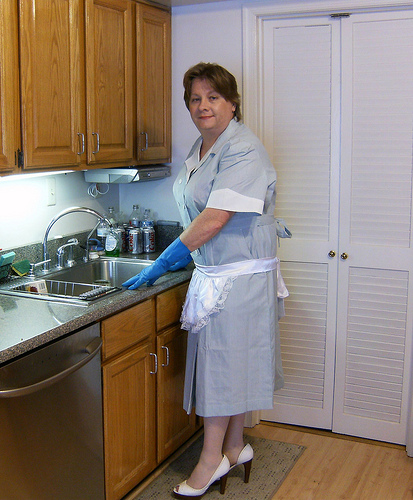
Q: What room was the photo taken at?
A: It was taken at the kitchen.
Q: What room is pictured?
A: It is a kitchen.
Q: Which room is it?
A: It is a kitchen.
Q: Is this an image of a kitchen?
A: Yes, it is showing a kitchen.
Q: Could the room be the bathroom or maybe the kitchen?
A: It is the kitchen.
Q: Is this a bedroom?
A: No, it is a kitchen.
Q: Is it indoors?
A: Yes, it is indoors.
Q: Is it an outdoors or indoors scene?
A: It is indoors.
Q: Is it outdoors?
A: No, it is indoors.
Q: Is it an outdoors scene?
A: No, it is indoors.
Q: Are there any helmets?
A: No, there are no helmets.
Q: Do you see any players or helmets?
A: No, there are no helmets or players.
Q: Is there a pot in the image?
A: No, there are no pots.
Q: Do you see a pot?
A: No, there are no pots.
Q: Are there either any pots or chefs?
A: No, there are no pots or chefs.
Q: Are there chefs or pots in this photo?
A: No, there are no pots or chefs.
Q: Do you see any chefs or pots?
A: No, there are no pots or chefs.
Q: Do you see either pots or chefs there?
A: No, there are no pots or chefs.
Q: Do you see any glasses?
A: No, there are no glasses.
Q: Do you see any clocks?
A: No, there are no clocks.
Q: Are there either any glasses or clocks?
A: No, there are no clocks or glasses.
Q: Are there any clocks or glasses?
A: No, there are no clocks or glasses.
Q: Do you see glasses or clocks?
A: No, there are no clocks or glasses.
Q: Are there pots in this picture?
A: No, there are no pots.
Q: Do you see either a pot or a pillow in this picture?
A: No, there are no pots or pillows.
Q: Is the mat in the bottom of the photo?
A: Yes, the mat is in the bottom of the image.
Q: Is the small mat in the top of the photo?
A: No, the mat is in the bottom of the image.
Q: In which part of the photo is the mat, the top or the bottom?
A: The mat is in the bottom of the image.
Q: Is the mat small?
A: Yes, the mat is small.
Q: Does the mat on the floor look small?
A: Yes, the mat is small.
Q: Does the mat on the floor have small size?
A: Yes, the mat is small.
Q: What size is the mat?
A: The mat is small.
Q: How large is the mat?
A: The mat is small.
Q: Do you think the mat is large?
A: No, the mat is small.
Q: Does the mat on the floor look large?
A: No, the mat is small.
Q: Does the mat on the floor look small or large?
A: The mat is small.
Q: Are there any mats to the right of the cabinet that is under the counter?
A: Yes, there is a mat to the right of the cabinet.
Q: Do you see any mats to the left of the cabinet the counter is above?
A: No, the mat is to the right of the cabinet.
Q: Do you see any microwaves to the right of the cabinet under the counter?
A: No, there is a mat to the right of the cabinet.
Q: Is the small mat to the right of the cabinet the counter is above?
A: Yes, the mat is to the right of the cabinet.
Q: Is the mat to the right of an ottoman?
A: No, the mat is to the right of the cabinet.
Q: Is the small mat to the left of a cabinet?
A: No, the mat is to the right of a cabinet.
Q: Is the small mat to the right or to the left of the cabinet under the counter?
A: The mat is to the right of the cabinet.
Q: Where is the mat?
A: The mat is on the floor.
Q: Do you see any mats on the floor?
A: Yes, there is a mat on the floor.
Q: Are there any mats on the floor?
A: Yes, there is a mat on the floor.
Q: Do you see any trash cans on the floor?
A: No, there is a mat on the floor.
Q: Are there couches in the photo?
A: No, there are no couches.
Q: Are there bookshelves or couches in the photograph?
A: No, there are no couches or bookshelves.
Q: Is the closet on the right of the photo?
A: Yes, the closet is on the right of the image.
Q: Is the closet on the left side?
A: No, the closet is on the right of the image.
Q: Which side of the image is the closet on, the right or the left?
A: The closet is on the right of the image.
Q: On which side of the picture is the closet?
A: The closet is on the right of the image.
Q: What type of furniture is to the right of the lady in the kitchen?
A: The piece of furniture is a closet.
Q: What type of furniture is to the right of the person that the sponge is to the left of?
A: The piece of furniture is a closet.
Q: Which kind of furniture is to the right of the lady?
A: The piece of furniture is a closet.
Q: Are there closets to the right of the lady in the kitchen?
A: Yes, there is a closet to the right of the lady.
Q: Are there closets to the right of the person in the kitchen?
A: Yes, there is a closet to the right of the lady.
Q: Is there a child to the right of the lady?
A: No, there is a closet to the right of the lady.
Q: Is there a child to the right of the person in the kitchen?
A: No, there is a closet to the right of the lady.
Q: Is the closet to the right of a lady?
A: Yes, the closet is to the right of a lady.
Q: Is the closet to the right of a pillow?
A: No, the closet is to the right of a lady.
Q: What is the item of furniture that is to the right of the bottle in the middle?
A: The piece of furniture is a closet.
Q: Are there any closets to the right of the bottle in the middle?
A: Yes, there is a closet to the right of the bottle.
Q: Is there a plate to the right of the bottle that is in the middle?
A: No, there is a closet to the right of the bottle.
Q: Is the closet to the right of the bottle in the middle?
A: Yes, the closet is to the right of the bottle.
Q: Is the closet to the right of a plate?
A: No, the closet is to the right of the bottle.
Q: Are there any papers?
A: No, there are no papers.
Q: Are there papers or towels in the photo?
A: No, there are no papers or towels.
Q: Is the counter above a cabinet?
A: Yes, the counter is above a cabinet.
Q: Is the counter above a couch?
A: No, the counter is above a cabinet.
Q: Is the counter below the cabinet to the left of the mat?
A: No, the counter is above the cabinet.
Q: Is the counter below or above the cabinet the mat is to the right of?
A: The counter is above the cabinet.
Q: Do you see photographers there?
A: No, there are no photographers.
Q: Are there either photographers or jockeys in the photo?
A: No, there are no photographers or jockeys.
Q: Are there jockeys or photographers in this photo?
A: No, there are no photographers or jockeys.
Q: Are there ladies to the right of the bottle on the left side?
A: Yes, there is a lady to the right of the bottle.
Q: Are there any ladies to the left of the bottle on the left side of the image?
A: No, the lady is to the right of the bottle.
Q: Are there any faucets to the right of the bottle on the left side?
A: No, there is a lady to the right of the bottle.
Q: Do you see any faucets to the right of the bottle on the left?
A: No, there is a lady to the right of the bottle.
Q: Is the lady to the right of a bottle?
A: Yes, the lady is to the right of a bottle.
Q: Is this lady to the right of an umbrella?
A: No, the lady is to the right of a bottle.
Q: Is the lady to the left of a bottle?
A: No, the lady is to the right of a bottle.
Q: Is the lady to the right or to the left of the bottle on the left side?
A: The lady is to the right of the bottle.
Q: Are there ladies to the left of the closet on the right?
A: Yes, there is a lady to the left of the closet.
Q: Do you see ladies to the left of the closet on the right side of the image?
A: Yes, there is a lady to the left of the closet.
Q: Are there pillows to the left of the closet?
A: No, there is a lady to the left of the closet.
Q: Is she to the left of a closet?
A: Yes, the lady is to the left of a closet.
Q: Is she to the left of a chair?
A: No, the lady is to the left of a closet.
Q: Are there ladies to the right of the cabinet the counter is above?
A: Yes, there is a lady to the right of the cabinet.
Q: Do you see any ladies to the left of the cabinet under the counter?
A: No, the lady is to the right of the cabinet.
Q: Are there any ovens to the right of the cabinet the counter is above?
A: No, there is a lady to the right of the cabinet.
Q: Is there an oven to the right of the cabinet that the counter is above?
A: No, there is a lady to the right of the cabinet.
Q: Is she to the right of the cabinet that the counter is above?
A: Yes, the lady is to the right of the cabinet.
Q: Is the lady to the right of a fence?
A: No, the lady is to the right of the cabinet.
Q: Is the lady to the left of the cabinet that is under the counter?
A: No, the lady is to the right of the cabinet.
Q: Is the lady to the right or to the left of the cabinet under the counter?
A: The lady is to the right of the cabinet.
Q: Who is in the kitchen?
A: The lady is in the kitchen.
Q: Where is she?
A: The lady is in the kitchen.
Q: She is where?
A: The lady is in the kitchen.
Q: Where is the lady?
A: The lady is in the kitchen.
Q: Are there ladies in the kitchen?
A: Yes, there is a lady in the kitchen.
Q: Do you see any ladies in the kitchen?
A: Yes, there is a lady in the kitchen.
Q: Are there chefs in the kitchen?
A: No, there is a lady in the kitchen.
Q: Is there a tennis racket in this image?
A: No, there are no rackets.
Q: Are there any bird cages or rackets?
A: No, there are no rackets or bird cages.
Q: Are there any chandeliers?
A: No, there are no chandeliers.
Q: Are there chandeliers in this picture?
A: No, there are no chandeliers.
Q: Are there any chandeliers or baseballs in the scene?
A: No, there are no chandeliers or baseballs.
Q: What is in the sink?
A: The drain is in the sink.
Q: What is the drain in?
A: The drain is in the sink.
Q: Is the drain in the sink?
A: Yes, the drain is in the sink.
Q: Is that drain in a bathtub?
A: No, the drain is in the sink.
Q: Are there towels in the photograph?
A: No, there are no towels.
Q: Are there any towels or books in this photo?
A: No, there are no towels or books.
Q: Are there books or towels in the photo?
A: No, there are no towels or books.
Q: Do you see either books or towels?
A: No, there are no towels or books.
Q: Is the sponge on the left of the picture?
A: Yes, the sponge is on the left of the image.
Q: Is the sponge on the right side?
A: No, the sponge is on the left of the image.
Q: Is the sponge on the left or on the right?
A: The sponge is on the left of the image.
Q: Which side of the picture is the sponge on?
A: The sponge is on the left of the image.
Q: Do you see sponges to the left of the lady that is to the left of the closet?
A: Yes, there is a sponge to the left of the lady.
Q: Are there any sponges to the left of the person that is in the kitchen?
A: Yes, there is a sponge to the left of the lady.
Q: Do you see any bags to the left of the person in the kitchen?
A: No, there is a sponge to the left of the lady.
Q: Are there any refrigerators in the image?
A: No, there are no refrigerators.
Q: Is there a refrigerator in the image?
A: No, there are no refrigerators.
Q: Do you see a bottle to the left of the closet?
A: Yes, there are bottles to the left of the closet.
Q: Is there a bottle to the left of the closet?
A: Yes, there are bottles to the left of the closet.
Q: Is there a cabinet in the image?
A: Yes, there is a cabinet.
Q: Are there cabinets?
A: Yes, there is a cabinet.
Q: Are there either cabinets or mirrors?
A: Yes, there is a cabinet.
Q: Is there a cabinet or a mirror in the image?
A: Yes, there is a cabinet.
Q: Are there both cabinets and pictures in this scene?
A: No, there is a cabinet but no pictures.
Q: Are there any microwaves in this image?
A: No, there are no microwaves.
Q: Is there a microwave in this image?
A: No, there are no microwaves.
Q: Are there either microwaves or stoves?
A: No, there are no microwaves or stoves.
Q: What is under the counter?
A: The cabinet is under the counter.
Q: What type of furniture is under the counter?
A: The piece of furniture is a cabinet.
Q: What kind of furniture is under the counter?
A: The piece of furniture is a cabinet.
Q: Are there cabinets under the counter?
A: Yes, there is a cabinet under the counter.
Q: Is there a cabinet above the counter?
A: No, the cabinet is under the counter.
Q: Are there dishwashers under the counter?
A: No, there is a cabinet under the counter.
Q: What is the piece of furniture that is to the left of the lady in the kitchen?
A: The piece of furniture is a cabinet.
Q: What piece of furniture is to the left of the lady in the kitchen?
A: The piece of furniture is a cabinet.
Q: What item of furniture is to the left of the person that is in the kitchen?
A: The piece of furniture is a cabinet.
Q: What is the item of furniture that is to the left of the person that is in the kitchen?
A: The piece of furniture is a cabinet.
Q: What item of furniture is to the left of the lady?
A: The piece of furniture is a cabinet.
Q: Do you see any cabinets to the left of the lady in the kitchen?
A: Yes, there is a cabinet to the left of the lady.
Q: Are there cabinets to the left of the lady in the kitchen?
A: Yes, there is a cabinet to the left of the lady.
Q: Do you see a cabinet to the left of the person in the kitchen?
A: Yes, there is a cabinet to the left of the lady.